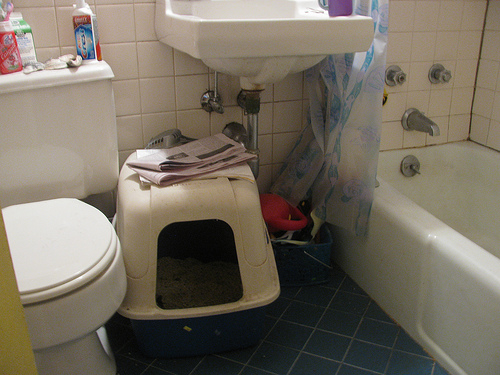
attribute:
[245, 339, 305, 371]
tile — Blue 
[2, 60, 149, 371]
toilet — White 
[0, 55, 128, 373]
toilet seat — down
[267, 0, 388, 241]
shower curtain — opaque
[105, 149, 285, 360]
box — litter, under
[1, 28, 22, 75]
container — white 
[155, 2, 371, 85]
sink — white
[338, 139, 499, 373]
tub — silver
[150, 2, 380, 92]
sink — white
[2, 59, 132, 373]
toilet — white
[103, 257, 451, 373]
floor — Blue 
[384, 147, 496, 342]
tub — White 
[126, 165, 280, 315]
litterbox — Plastic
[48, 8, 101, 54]
toothpaste — crest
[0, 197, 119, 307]
toilet seat — white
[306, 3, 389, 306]
shower curtain — Blue 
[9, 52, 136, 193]
tank — against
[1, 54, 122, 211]
tank — white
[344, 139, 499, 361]
bathtub — white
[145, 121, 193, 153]
scooper — gray, plastic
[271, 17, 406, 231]
curtain — plastic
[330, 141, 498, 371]
bathtub — white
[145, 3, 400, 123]
sink — white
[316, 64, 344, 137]
pattern — light blue